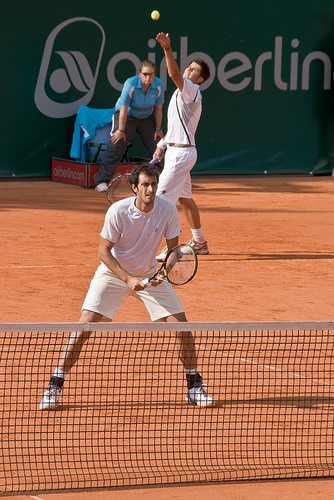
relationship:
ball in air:
[149, 9, 162, 22] [0, 0, 334, 324]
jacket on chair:
[70, 106, 120, 162] [70, 106, 130, 166]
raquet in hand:
[140, 245, 197, 298] [127, 275, 145, 291]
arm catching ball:
[154, 32, 197, 102] [149, 9, 162, 22]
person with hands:
[93, 60, 166, 192] [109, 129, 167, 145]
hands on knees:
[109, 129, 167, 145] [108, 130, 166, 155]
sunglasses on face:
[143, 71, 156, 78] [141, 64, 155, 87]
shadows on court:
[0, 174, 331, 213] [0, 173, 331, 499]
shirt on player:
[100, 197, 179, 275] [39, 164, 216, 408]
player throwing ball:
[153, 32, 210, 261] [149, 9, 162, 22]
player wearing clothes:
[39, 164, 216, 408] [82, 196, 187, 323]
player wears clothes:
[39, 164, 216, 408] [82, 196, 187, 323]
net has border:
[0, 321, 334, 497] [0, 320, 334, 333]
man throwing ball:
[153, 32, 210, 261] [149, 9, 162, 22]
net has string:
[0, 321, 334, 497] [0, 330, 333, 495]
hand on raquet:
[127, 275, 145, 291] [140, 245, 197, 298]